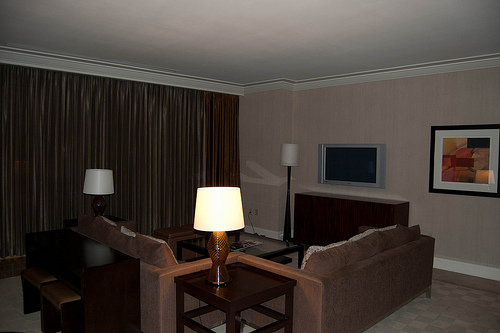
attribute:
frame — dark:
[428, 132, 435, 195]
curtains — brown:
[2, 64, 244, 165]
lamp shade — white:
[279, 142, 299, 167]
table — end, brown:
[135, 167, 408, 332]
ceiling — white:
[4, 4, 499, 81]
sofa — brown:
[237, 220, 437, 331]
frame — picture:
[415, 113, 497, 220]